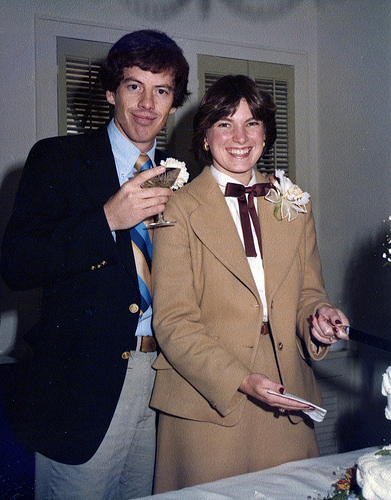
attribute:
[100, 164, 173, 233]
hand — right hand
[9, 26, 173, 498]
man — standing close , behind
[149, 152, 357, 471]
suit — light brown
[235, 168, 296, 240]
bow tie — burgundy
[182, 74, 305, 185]
woman's face — grinning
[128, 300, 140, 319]
button — gold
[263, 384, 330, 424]
napkin — white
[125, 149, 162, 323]
tie — gold , blue 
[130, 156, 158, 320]
tie — blue , brown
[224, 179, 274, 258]
ribbon — brown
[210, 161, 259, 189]
neck — woman's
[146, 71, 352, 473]
woman — dressed, posing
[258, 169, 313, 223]
flower — white, decorative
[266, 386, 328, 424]
handkerchief — white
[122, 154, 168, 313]
tie — gold and blue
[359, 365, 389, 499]
white cake — multi level 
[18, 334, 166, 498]
slacks — grey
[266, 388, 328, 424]
napkin — white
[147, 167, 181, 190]
drinking glass — fancy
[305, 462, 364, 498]
flowers — variety 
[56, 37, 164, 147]
shutters — two paneled, window shutters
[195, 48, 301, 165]
shutters — two paneled, window shutters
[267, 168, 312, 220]
flower — white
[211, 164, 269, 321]
shirt — white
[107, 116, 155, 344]
shirt — light blue, dressy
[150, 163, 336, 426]
jacket — brown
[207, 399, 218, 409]
button — brown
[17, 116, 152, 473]
blazer — black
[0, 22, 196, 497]
man — holding , posing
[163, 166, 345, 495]
suit — beige suit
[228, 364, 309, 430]
hand — woman's hand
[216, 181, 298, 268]
ribbon — dark 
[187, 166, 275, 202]
collar — woman's collar